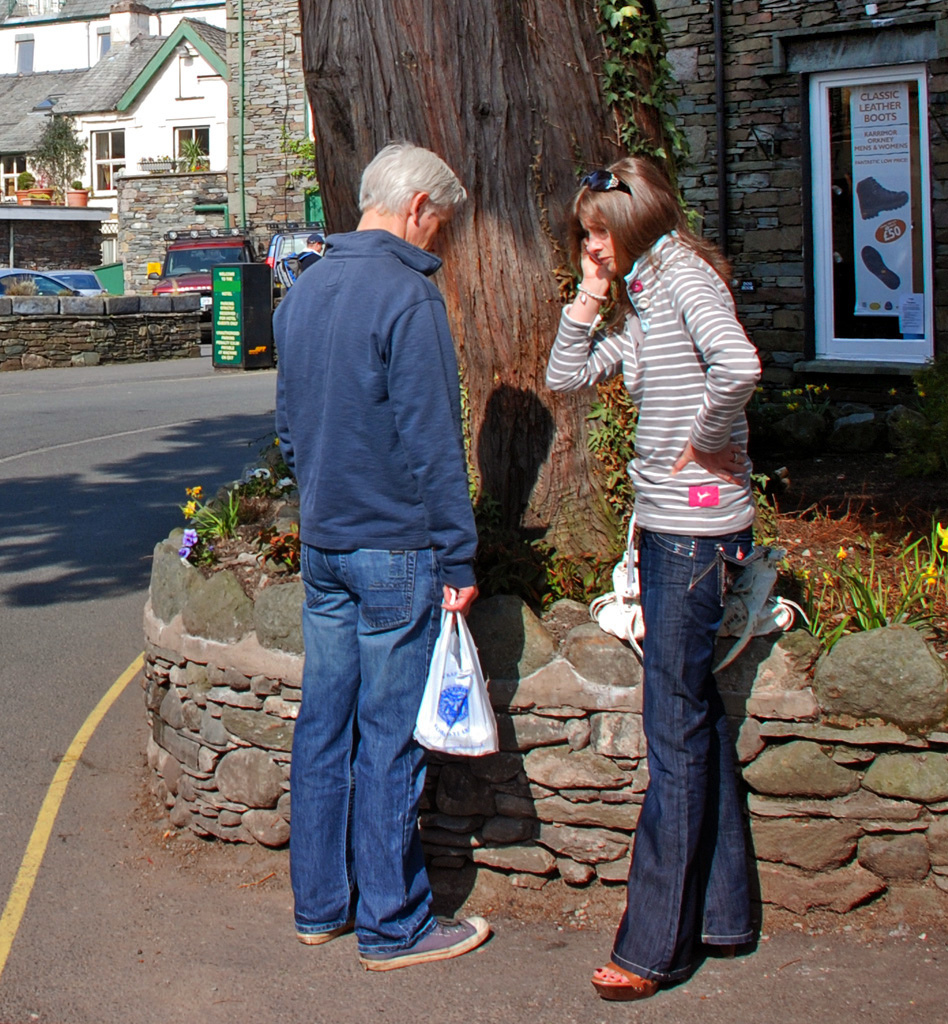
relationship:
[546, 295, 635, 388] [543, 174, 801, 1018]
arm of a woman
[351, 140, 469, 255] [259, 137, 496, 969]
head of man